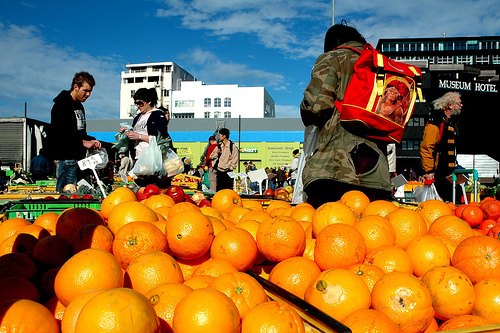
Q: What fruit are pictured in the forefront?
A: Oranges.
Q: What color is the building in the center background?
A: White.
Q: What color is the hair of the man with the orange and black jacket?
A: Grey.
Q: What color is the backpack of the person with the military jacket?
A: Red and yellow.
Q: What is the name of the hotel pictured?
A: Museum Hotel.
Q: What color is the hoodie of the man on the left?
A: Black.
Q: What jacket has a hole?
A: The camouflage jacket.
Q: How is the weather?
A: Sunny.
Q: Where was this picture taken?
A: Market.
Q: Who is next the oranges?
A: A man with a red backpack.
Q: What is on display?
A: Sizable oranges.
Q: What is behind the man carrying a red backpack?
A: Large pile of oranges.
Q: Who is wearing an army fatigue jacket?
A: The man carrying the red back pack.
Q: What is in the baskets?
A: Piles of oranges.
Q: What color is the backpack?
A: Red and yellow graphic.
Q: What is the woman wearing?
A: A camo jacket.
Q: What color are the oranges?
A: Orange.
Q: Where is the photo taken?
A: During a market.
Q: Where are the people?
A: Behind the oranges.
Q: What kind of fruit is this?
A: The fruit are oranges.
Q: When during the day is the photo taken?
A: During the daytime.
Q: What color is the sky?
A: Blue.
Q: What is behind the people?
A: A building.